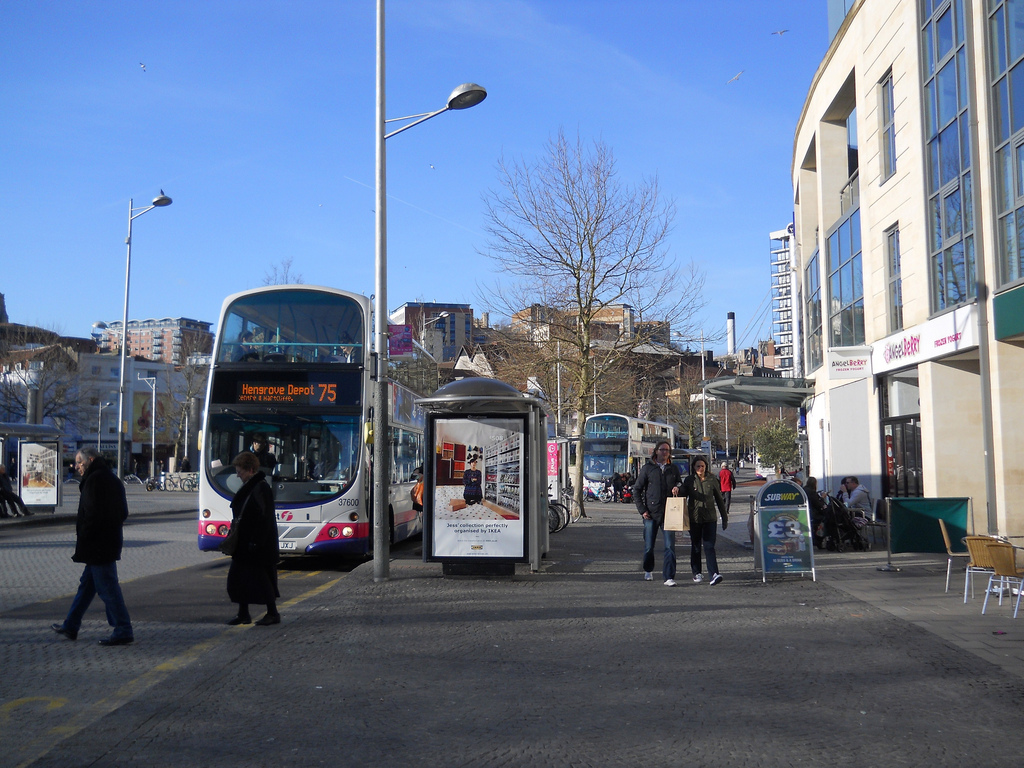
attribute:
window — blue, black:
[860, 70, 924, 189]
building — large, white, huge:
[783, 69, 991, 471]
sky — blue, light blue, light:
[107, 14, 352, 176]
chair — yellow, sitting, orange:
[924, 517, 1009, 627]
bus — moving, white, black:
[223, 305, 392, 579]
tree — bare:
[501, 123, 710, 291]